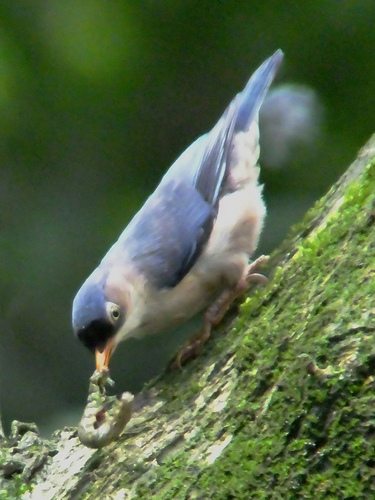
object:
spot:
[78, 317, 116, 354]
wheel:
[212, 216, 262, 241]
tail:
[106, 391, 134, 436]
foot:
[170, 253, 270, 370]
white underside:
[213, 124, 266, 291]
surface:
[0, 132, 375, 500]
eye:
[108, 304, 121, 322]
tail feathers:
[223, 48, 285, 144]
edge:
[273, 48, 284, 64]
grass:
[198, 316, 375, 500]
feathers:
[130, 128, 260, 331]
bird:
[72, 49, 284, 374]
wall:
[142, 53, 195, 92]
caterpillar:
[77, 368, 133, 448]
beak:
[95, 347, 111, 371]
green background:
[2, 0, 375, 432]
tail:
[221, 49, 284, 137]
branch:
[166, 254, 271, 374]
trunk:
[0, 137, 375, 500]